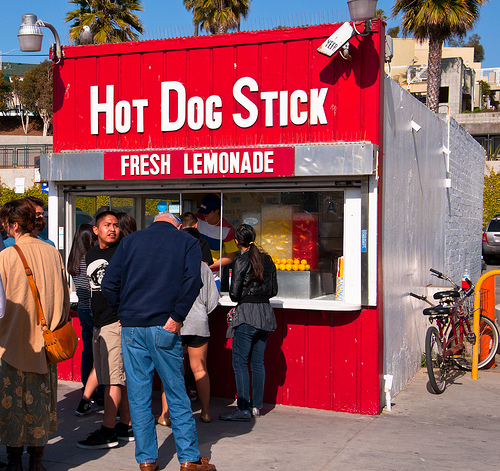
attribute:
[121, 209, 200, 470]
person — standing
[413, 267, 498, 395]
bicycle — parked, red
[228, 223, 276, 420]
girl — standing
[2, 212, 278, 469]
people — standing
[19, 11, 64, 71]
light — small, overhead, hanging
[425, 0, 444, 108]
tree — lush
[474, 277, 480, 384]
pole — yellow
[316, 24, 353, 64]
camera — security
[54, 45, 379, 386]
building — restaurant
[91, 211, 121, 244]
man — looking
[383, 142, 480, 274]
wall — white